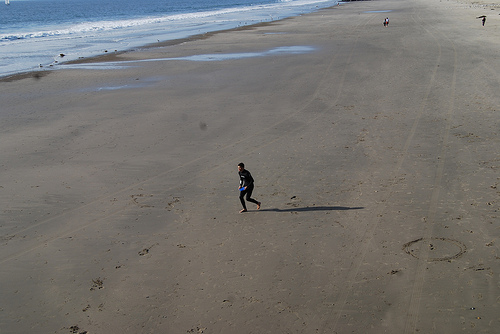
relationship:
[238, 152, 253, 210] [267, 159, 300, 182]
man on beach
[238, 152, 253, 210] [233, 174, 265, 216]
man in wet sujit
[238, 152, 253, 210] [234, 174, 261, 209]
man in wet suit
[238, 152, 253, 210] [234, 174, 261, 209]
man running in wet suit